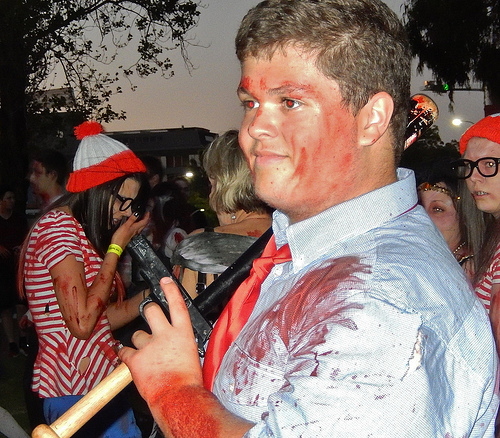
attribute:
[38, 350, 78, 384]
stripe — red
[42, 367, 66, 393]
stripe — red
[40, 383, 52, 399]
stripe — red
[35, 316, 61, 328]
stripe — red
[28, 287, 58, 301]
stripe — red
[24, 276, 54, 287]
stripe — red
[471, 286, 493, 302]
stripe — red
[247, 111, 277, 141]
nose — person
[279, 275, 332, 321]
blood — fake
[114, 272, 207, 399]
hand — person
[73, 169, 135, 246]
head — girl's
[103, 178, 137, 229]
face — girl's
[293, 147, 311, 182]
blood — fake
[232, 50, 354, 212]
face — his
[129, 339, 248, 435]
arms — his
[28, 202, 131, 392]
shirt — red, white, stripe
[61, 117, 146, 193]
hat — red, white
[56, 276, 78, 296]
blood — fake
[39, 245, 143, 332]
arms — her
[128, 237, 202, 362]
gun — toy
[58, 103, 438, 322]
bat — baseball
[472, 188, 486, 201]
teeth — fake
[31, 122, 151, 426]
girl — dressed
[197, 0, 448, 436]
kid — fat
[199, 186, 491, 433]
shirt — white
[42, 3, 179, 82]
branches — tree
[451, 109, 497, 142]
beanie — orange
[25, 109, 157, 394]
girl —  gold band 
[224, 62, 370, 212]
red paint — red 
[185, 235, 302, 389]
red tie — red 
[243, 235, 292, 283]
loose knot — loose 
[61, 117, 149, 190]
cap — red, white 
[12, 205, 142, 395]
striped shirt — white , red, striped 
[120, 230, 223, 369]
hand gun — black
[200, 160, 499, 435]
shirt — red and white